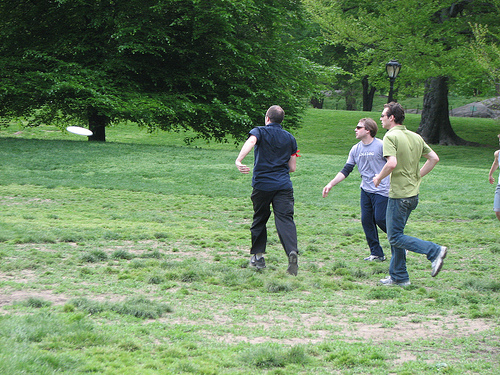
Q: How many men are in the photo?
A: Three.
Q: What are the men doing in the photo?
A: Playing frisbee.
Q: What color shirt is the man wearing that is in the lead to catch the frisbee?
A: Blue.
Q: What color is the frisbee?
A: White.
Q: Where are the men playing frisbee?
A: In the park.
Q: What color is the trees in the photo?
A: Green.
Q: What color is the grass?
A: Green.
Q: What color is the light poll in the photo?
A: Black.